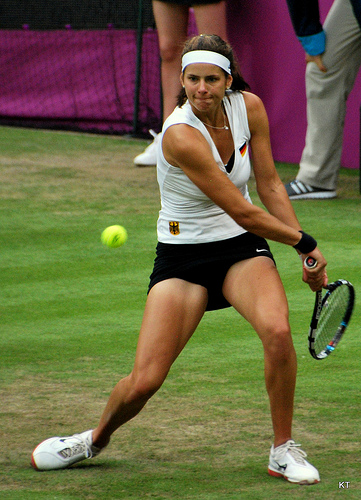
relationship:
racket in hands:
[297, 269, 347, 362] [291, 238, 334, 291]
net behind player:
[0, 2, 175, 133] [85, 33, 359, 440]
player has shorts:
[30, 35, 328, 484] [142, 236, 294, 325]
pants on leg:
[291, 0, 359, 185] [285, 0, 361, 201]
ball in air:
[101, 224, 128, 247] [83, 224, 136, 300]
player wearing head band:
[30, 35, 328, 484] [181, 49, 232, 76]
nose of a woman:
[196, 80, 210, 96] [161, 33, 263, 157]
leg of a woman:
[227, 260, 337, 496] [0, 33, 344, 491]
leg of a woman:
[24, 262, 226, 469] [0, 33, 344, 491]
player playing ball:
[30, 35, 328, 484] [101, 224, 128, 247]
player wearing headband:
[30, 35, 328, 484] [166, 40, 240, 74]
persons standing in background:
[147, 0, 341, 167] [5, 5, 356, 115]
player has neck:
[28, 35, 326, 464] [191, 95, 226, 120]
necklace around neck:
[188, 101, 230, 129] [191, 95, 226, 120]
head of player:
[179, 34, 231, 108] [30, 35, 328, 484]